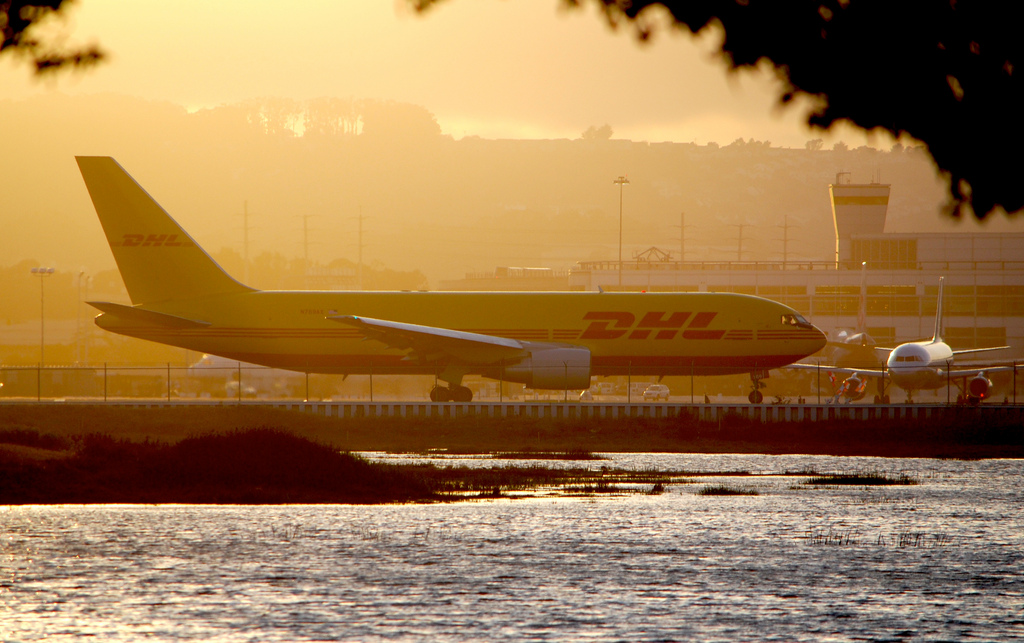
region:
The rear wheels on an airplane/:
[392, 342, 514, 429]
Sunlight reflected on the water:
[8, 410, 639, 641]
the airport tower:
[825, 163, 905, 265]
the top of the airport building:
[572, 248, 1021, 296]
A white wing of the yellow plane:
[326, 311, 582, 379]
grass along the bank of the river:
[82, 431, 471, 498]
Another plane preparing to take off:
[856, 289, 1022, 378]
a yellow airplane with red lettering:
[72, 149, 866, 403]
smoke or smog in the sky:
[21, 7, 515, 249]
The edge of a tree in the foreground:
[648, 17, 1021, 201]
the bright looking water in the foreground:
[50, 501, 1021, 603]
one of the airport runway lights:
[27, 267, 76, 403]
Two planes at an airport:
[66, 121, 1022, 435]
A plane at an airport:
[65, 129, 837, 405]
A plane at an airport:
[827, 266, 1017, 402]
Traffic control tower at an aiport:
[815, 158, 1013, 314]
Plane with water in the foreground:
[57, 143, 845, 625]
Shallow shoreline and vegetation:
[111, 421, 919, 510]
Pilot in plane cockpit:
[758, 287, 828, 364]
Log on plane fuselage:
[565, 291, 838, 353]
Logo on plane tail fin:
[69, 121, 265, 299]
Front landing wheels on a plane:
[738, 352, 778, 407]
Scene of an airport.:
[8, 0, 999, 621]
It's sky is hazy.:
[41, 40, 811, 316]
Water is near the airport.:
[12, 504, 913, 628]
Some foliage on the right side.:
[688, 10, 1022, 181]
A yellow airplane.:
[65, 125, 835, 446]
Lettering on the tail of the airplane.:
[41, 128, 297, 356]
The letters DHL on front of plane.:
[521, 215, 831, 468]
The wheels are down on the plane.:
[366, 307, 812, 425]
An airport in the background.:
[556, 140, 1015, 344]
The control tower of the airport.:
[754, 125, 970, 318]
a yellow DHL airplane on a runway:
[72, 152, 826, 412]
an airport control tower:
[837, 167, 891, 272]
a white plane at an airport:
[776, 277, 1014, 402]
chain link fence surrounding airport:
[5, 366, 1023, 415]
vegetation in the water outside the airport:
[5, 417, 942, 515]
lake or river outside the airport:
[8, 436, 1021, 639]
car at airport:
[641, 382, 670, 405]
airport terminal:
[560, 176, 1019, 367]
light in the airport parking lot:
[21, 259, 57, 380]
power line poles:
[656, 211, 802, 270]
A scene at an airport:
[16, 7, 1007, 535]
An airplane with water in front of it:
[66, 146, 823, 619]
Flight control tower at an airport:
[773, 153, 1015, 275]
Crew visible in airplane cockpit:
[768, 300, 829, 368]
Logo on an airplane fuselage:
[575, 287, 835, 346]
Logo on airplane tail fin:
[68, 145, 253, 300]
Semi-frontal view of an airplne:
[830, 273, 1017, 400]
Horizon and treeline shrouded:
[32, 12, 997, 162]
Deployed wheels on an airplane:
[411, 354, 482, 416]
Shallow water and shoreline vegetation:
[84, 423, 948, 515]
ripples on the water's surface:
[327, 526, 555, 602]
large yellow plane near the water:
[59, 144, 838, 395]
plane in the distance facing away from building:
[806, 273, 1022, 409]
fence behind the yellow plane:
[27, 358, 221, 403]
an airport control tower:
[822, 163, 892, 261]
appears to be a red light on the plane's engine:
[962, 372, 997, 405]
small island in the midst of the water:
[43, 415, 480, 520]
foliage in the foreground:
[735, 1, 1021, 216]